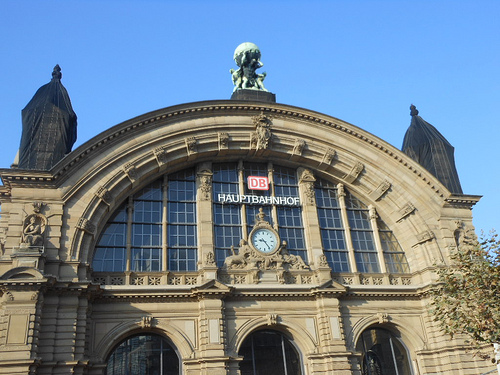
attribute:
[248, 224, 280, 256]
clock — white, here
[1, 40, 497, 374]
building — large, brick, old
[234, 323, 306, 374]
opening — arched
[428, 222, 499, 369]
tree — green,  outside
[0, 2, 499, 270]
sky — blue, clear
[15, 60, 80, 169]
covering — black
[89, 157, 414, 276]
window — huge, arched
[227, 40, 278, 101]
statue — gargoyle, green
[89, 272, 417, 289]
railing — concrete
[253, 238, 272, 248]
hands — black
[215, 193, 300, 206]
name — red, white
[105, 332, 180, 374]
doorway — arched